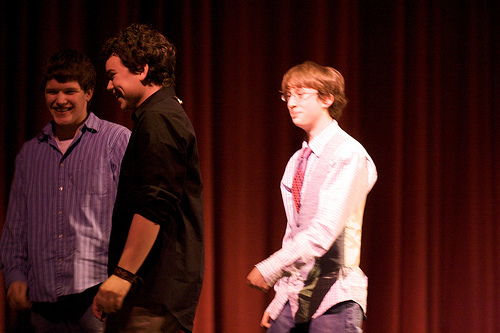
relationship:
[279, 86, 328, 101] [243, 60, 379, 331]
glasses on boy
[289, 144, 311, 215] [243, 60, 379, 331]
red tie on boy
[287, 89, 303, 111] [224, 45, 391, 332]
nose of a boy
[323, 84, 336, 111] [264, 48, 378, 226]
ear of boy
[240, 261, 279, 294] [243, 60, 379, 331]
hand of a boy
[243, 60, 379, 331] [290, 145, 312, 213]
boy has a tie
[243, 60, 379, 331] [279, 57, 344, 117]
boy has hair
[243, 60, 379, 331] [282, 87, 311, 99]
boy glasses glasses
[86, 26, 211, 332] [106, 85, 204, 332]
boy wears a black shirt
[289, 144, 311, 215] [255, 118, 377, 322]
red tie on shirt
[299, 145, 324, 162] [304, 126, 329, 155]
knot under collar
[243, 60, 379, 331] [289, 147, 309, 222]
boy wearing tie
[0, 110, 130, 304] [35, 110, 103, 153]
shirt has collar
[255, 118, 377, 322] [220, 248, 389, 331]
shirt untucked from pants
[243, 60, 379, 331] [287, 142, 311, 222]
boy wearing red tie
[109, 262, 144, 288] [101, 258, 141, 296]
band on wrist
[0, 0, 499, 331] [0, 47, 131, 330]
curtains behind boy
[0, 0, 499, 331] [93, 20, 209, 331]
curtains behind boy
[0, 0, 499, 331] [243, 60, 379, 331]
curtains behind boy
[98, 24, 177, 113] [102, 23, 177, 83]
head has curly hair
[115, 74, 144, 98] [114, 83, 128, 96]
cheek has dimple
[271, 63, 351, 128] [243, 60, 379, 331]
head on boy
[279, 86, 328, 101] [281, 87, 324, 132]
glasses on face